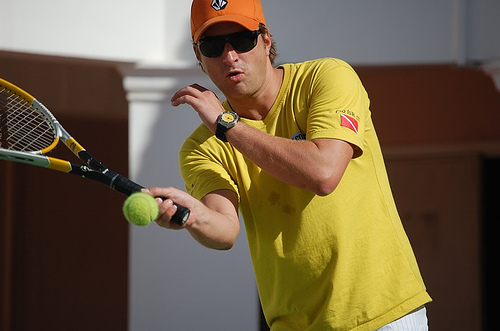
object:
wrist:
[214, 114, 240, 143]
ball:
[118, 190, 162, 229]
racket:
[0, 75, 191, 228]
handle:
[100, 163, 192, 241]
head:
[0, 76, 85, 182]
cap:
[180, 0, 266, 50]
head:
[182, 0, 287, 101]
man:
[145, 1, 446, 331]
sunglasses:
[189, 29, 260, 57]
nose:
[219, 41, 240, 65]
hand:
[157, 76, 234, 131]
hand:
[140, 190, 203, 231]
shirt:
[173, 50, 438, 330]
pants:
[355, 303, 436, 331]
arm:
[169, 83, 358, 198]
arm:
[134, 185, 247, 254]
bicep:
[203, 193, 240, 221]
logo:
[334, 109, 373, 133]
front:
[192, 11, 259, 43]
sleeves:
[299, 51, 375, 158]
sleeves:
[175, 142, 240, 206]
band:
[216, 122, 226, 140]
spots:
[275, 200, 298, 216]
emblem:
[208, 0, 229, 12]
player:
[145, 32, 377, 260]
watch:
[196, 105, 248, 147]